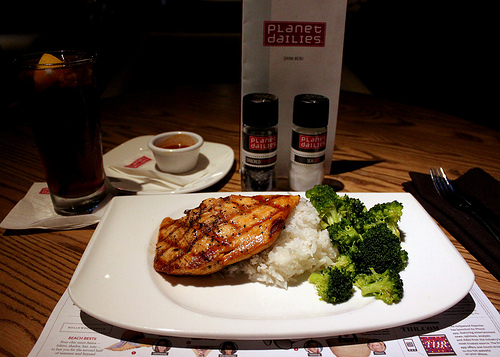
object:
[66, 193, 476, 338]
plate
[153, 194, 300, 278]
chicken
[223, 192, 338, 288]
rice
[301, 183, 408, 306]
broccoli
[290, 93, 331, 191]
salt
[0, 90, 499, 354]
table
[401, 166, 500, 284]
napkin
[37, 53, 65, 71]
lemon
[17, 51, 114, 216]
glass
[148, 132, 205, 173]
sauce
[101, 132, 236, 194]
saucer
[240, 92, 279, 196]
pepper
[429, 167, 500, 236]
fork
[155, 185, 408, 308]
meal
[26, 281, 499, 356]
paper